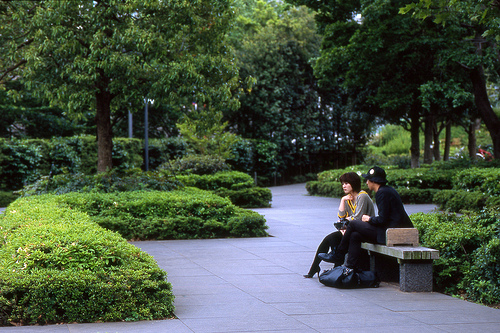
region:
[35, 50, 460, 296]
man and woman seated on bench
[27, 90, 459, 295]
couple in a landscaped park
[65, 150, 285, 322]
angled edges of bushes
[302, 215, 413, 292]
black bag sitting on ground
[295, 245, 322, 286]
woman wearing a high-heeled shoe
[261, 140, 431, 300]
man and woman leaning forward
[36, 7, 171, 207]
tree trunk surrounded by plants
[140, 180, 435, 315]
path lined with cement blocks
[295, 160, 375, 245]
woman with hand under her chin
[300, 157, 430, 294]
man turned toward woman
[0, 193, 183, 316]
Low cut green hedges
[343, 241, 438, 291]
concrete park bench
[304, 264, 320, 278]
dark colored high heel shoe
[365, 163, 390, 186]
dark cat on a man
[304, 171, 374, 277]
Woman with short brown hair sitting down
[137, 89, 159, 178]
light pole in the background.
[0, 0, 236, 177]
Large tree in park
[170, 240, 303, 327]
Large walkway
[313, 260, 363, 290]
Large black purse on ground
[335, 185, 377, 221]
gray sweater with yellow trim on neck and sleeves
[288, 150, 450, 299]
Two people are in a park.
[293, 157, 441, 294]
The people are sitting.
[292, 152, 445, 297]
The people sit on a stone bench.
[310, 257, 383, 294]
A bag is on the ground.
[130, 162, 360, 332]
A pathway leads through the park.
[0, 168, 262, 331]
The park has many lush bushes.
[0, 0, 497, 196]
The park has several trees.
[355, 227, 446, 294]
The bench is made of stone.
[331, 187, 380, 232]
The woman wears a gray top.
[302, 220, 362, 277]
The woman wears black pants.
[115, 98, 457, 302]
people on a bench in a park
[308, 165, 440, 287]
man and woman on stone bench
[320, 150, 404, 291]
man and woman talking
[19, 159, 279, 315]
neatly trimmed green bushes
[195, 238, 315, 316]
cement walkway curves through ladscaping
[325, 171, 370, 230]
woman wearing beige and yellow sweater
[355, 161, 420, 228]
man in black wearing black hat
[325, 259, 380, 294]
black bag on cement sidewalk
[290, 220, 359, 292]
man and woman wearing black shoes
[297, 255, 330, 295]
woman wearing black high heels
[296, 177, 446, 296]
Two people sitting in the park.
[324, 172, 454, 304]
Two people are sitting on a bench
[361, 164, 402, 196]
A person is wearing a hat.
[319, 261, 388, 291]
A black backpack lays on the ground.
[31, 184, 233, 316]
The bushes in the park is trimmed.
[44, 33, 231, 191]
A tree sits across from the people on the bench.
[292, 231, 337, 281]
The lady has on black pants.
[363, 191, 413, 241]
The man with the hat on is wearing a black shirt.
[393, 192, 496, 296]
The bench is in front of the bushes.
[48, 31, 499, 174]
The park is surrounded by trees.